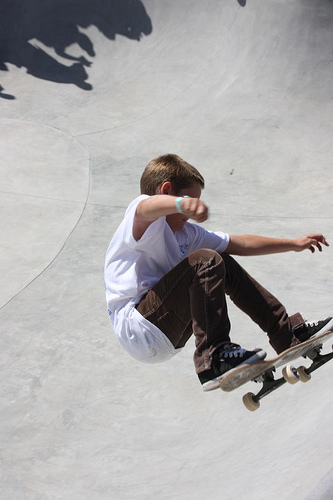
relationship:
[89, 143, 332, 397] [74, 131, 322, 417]
boy jumping in air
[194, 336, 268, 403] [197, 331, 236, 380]
shoe on foot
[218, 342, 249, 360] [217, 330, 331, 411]
laces on shoes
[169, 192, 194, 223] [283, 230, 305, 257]
blue band on wrist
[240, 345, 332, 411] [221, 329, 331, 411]
wheels on skateboard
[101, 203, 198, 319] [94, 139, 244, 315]
t-shirt on boy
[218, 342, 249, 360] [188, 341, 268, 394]
laces on shoe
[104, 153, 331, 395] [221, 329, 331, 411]
boy riding skateboard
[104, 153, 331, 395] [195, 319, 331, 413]
boy on skateboard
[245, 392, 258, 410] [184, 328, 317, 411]
wheel on skateboard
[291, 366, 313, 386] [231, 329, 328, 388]
wheel on skateboard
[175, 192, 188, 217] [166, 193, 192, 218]
blue band on wrist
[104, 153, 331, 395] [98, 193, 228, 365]
boy wearing t-shirt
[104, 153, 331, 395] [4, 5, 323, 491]
boy skating on skate ramp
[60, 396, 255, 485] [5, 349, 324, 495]
cement covering ground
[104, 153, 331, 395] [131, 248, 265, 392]
boy has leg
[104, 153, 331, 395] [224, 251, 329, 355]
boy has leg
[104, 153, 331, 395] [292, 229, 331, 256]
boy has hand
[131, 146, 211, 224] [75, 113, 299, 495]
head of a boy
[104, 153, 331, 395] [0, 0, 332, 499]
boy skateboarding in a skate bowl